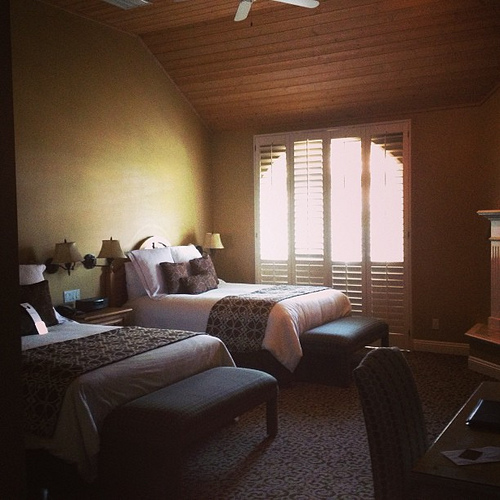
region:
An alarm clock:
[80, 293, 106, 314]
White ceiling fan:
[165, 0, 323, 31]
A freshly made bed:
[23, 280, 124, 465]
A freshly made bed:
[155, 255, 295, 365]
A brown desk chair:
[360, 352, 435, 492]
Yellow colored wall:
[55, 100, 191, 220]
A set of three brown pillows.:
[165, 262, 213, 287]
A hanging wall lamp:
[55, 237, 80, 272]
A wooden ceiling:
[205, 35, 441, 93]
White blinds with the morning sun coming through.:
[267, 141, 411, 281]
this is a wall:
[25, 62, 115, 164]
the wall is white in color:
[50, 67, 135, 172]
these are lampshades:
[49, 236, 124, 272]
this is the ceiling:
[243, 44, 370, 79]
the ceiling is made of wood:
[280, 32, 373, 78]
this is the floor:
[276, 438, 333, 497]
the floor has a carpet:
[296, 392, 345, 497]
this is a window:
[265, 147, 400, 272]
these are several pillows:
[163, 256, 216, 287]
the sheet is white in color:
[163, 301, 187, 318]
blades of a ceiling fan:
[226, 2, 325, 22]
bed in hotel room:
[130, 242, 337, 349]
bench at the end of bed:
[98, 355, 308, 456]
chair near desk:
[359, 344, 439, 499]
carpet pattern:
[236, 438, 348, 490]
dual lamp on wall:
[56, 237, 128, 275]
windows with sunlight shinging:
[263, 183, 421, 298]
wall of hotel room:
[411, 191, 483, 358]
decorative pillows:
[164, 255, 226, 296]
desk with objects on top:
[412, 376, 496, 496]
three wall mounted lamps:
[40, 218, 237, 272]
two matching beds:
[15, 213, 408, 468]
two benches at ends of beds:
[76, 286, 419, 498]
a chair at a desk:
[336, 321, 498, 495]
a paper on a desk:
[436, 439, 498, 484]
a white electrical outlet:
[58, 280, 106, 318]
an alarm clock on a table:
[64, 291, 154, 331]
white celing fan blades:
[218, 1, 338, 54]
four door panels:
[236, 98, 436, 345]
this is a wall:
[66, 60, 138, 207]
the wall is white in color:
[96, 130, 121, 192]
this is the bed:
[156, 250, 257, 324]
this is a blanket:
[218, 284, 279, 324]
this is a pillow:
[136, 255, 167, 273]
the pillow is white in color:
[136, 246, 158, 277]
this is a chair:
[362, 355, 424, 438]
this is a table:
[429, 419, 499, 456]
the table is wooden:
[435, 429, 459, 441]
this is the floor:
[277, 440, 344, 473]